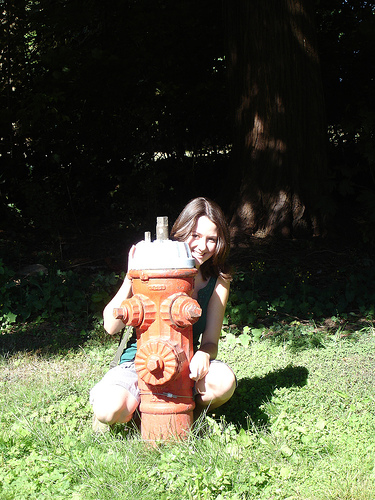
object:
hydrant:
[114, 215, 202, 441]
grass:
[2, 288, 371, 499]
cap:
[129, 217, 195, 272]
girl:
[90, 198, 236, 435]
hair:
[170, 198, 230, 281]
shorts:
[104, 355, 237, 402]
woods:
[244, 37, 296, 210]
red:
[134, 272, 188, 292]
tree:
[245, 2, 318, 250]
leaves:
[0, 0, 76, 135]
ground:
[0, 269, 374, 499]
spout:
[161, 293, 201, 328]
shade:
[5, 174, 375, 356]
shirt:
[119, 271, 219, 362]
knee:
[90, 383, 129, 423]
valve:
[134, 341, 176, 385]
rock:
[35, 263, 48, 272]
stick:
[285, 314, 309, 323]